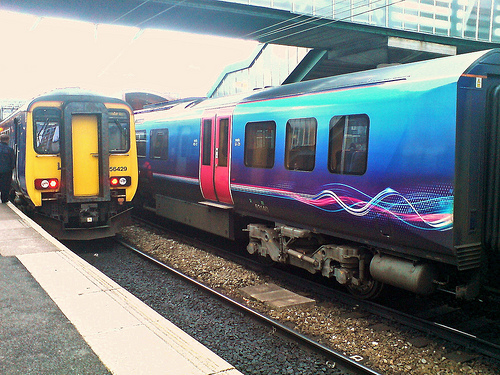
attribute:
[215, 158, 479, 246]
wave — blue, pink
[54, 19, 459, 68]
bridge — metal, blue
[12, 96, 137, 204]
train — yellow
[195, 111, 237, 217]
doors on a train — red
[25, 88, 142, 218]
front of a train — black,  yellow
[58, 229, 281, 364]
brown bricks — light brown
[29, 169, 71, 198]
headlights on train — red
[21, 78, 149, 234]
black train — yellow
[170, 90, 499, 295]
train is blue — red